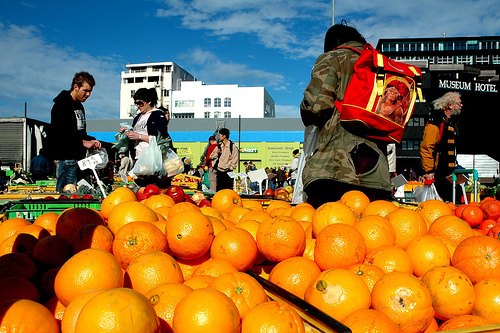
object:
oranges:
[54, 248, 125, 308]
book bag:
[336, 43, 423, 145]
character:
[374, 85, 406, 126]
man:
[48, 71, 103, 195]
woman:
[117, 88, 178, 188]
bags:
[133, 135, 167, 180]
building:
[119, 61, 276, 120]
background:
[0, 0, 500, 199]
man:
[419, 90, 466, 205]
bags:
[413, 183, 444, 203]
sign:
[435, 76, 500, 94]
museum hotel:
[436, 79, 499, 93]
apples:
[165, 185, 186, 203]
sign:
[76, 153, 108, 199]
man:
[299, 20, 424, 211]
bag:
[75, 147, 111, 171]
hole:
[348, 142, 379, 176]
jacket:
[299, 41, 395, 193]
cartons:
[7, 202, 102, 220]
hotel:
[372, 36, 498, 184]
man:
[209, 127, 240, 197]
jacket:
[211, 140, 239, 173]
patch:
[345, 142, 384, 177]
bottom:
[301, 142, 392, 191]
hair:
[431, 91, 462, 111]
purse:
[155, 130, 171, 154]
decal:
[375, 75, 412, 127]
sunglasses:
[133, 100, 145, 107]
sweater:
[47, 89, 97, 160]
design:
[73, 109, 86, 130]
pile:
[0, 183, 499, 333]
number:
[81, 160, 86, 167]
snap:
[376, 65, 386, 78]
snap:
[414, 75, 424, 88]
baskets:
[244, 268, 354, 333]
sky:
[1, 0, 497, 119]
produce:
[0, 182, 500, 333]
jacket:
[419, 110, 460, 173]